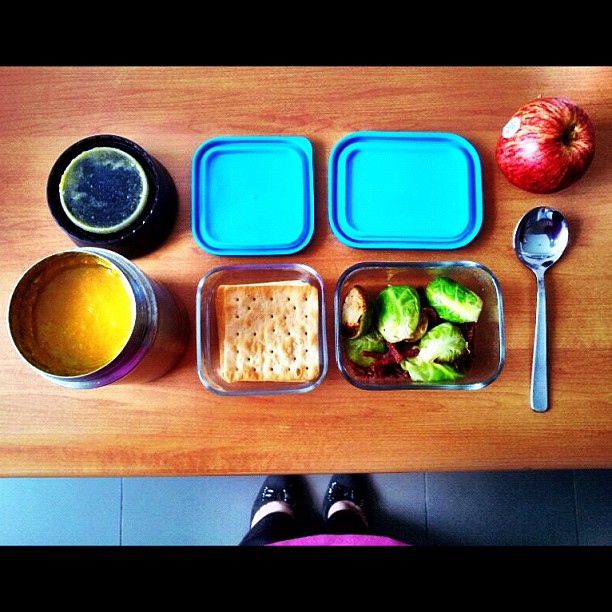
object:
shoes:
[254, 475, 365, 506]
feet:
[252, 474, 376, 523]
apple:
[496, 98, 595, 195]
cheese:
[35, 266, 106, 370]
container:
[5, 247, 189, 390]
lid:
[190, 135, 314, 257]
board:
[0, 62, 611, 474]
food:
[6, 98, 596, 397]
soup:
[21, 250, 131, 376]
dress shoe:
[322, 474, 361, 524]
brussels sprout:
[341, 286, 368, 339]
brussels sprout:
[373, 285, 420, 344]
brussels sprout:
[426, 276, 483, 324]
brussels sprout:
[421, 323, 467, 361]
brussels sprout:
[400, 357, 465, 382]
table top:
[0, 66, 611, 477]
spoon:
[513, 205, 569, 412]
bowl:
[333, 258, 505, 392]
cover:
[44, 133, 180, 259]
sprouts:
[342, 276, 484, 383]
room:
[0, 0, 611, 611]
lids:
[191, 134, 315, 258]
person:
[238, 473, 414, 546]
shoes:
[247, 472, 369, 526]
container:
[195, 262, 328, 397]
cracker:
[216, 280, 320, 383]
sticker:
[502, 116, 521, 139]